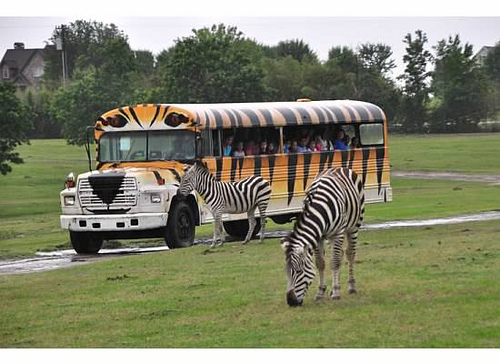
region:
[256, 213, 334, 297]
the zebra is stripped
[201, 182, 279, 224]
the zebra has white and black stripes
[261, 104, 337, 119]
the bus is stripped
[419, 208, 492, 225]
the road is wet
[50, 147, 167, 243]
the bus has a white bonnet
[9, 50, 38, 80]
an oldhouse is at the background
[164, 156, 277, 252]
the zebra is near the truck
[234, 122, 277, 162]
the children are staring at the animals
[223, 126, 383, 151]
the lorry has no windows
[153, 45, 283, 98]
the tree has dark green leaves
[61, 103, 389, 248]
a bus painted as a tiger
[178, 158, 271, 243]
a zebra in a field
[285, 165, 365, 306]
a zebra in a field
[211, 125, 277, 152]
people looking out of a bus window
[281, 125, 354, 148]
people looking out of a bus window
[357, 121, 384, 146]
rear window on a bus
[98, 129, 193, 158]
windshield of a bus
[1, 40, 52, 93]
a house cloaked by trees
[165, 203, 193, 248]
front wheel on a bus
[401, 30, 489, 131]
trees in the distance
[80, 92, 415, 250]
A bus painted to look like a tiger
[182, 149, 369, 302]
Two zebras standing in the grass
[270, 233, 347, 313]
The zebra is eating the grass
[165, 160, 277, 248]
The zebra is examining the bus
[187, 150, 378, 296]
The zebras are black and white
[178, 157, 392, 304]
The zebras have black stripes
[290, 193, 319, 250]
A short mane on the zebra's back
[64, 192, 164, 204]
Two head lights on the front of the bus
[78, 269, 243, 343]
Short green grass grows on the ground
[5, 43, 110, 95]
A building behind the trees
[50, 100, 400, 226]
bus painted link a tiger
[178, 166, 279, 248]
zebra in front of the bus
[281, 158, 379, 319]
zebra eating grass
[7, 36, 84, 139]
house in the background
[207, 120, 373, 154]
people watching the zebras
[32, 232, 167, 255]
puddle of water under the bus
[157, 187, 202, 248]
front left tire of the bus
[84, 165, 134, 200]
nose painted on the bus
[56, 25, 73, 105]
utility pole in the background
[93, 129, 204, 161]
windows of the bus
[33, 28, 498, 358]
a bus driving in a field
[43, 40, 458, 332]
a zebra walking by a bus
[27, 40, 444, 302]
a bus with black stripes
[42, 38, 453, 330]
a yellow bus with black stripes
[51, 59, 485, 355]
a bus driving in on path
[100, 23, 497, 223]
kids looking out the window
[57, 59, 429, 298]
kids looking out the bus window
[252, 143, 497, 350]
zebra eating the grass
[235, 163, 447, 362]
a zebra is eating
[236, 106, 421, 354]
a zebra eatting in a field